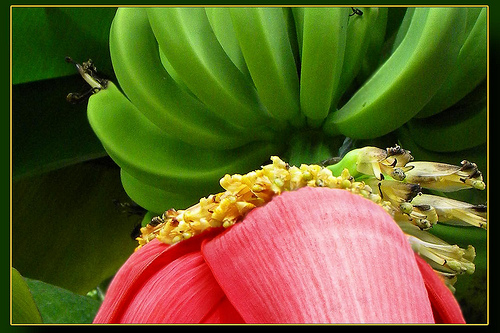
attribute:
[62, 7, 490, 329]
flower — bloomed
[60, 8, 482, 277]
bananas — huge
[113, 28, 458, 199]
green stem — flower petals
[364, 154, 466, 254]
flower — multiple, yellow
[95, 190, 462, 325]
plant — red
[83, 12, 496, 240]
bananas — green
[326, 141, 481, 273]
bananas — green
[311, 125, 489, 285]
petal — green, black and yellow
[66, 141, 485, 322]
plant — red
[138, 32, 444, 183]
petals — multiple, green, flower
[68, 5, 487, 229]
bananas — green, on plant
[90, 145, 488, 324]
flower — curved, green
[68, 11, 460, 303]
plantains — green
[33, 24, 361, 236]
plantains — green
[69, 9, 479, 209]
bananas — green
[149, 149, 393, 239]
seeds — yellow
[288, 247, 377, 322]
lines — small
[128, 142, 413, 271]
flower — red